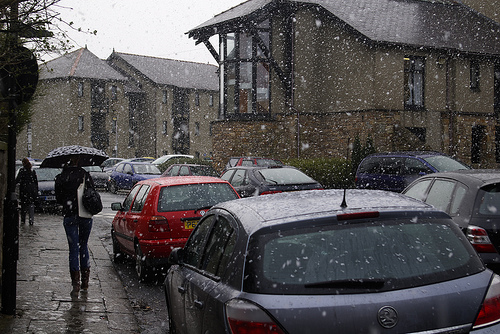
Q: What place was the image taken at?
A: It was taken at the street.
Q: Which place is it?
A: It is a street.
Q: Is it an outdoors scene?
A: Yes, it is outdoors.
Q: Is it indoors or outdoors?
A: It is outdoors.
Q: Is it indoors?
A: No, it is outdoors.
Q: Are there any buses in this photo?
A: No, there are no buses.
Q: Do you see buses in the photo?
A: No, there are no buses.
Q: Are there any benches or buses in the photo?
A: No, there are no buses or benches.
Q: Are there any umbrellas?
A: Yes, there is an umbrella.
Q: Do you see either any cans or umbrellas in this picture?
A: Yes, there is an umbrella.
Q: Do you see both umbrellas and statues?
A: No, there is an umbrella but no statues.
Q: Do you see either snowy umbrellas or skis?
A: Yes, there is a snowy umbrella.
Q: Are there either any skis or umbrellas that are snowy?
A: Yes, the umbrella is snowy.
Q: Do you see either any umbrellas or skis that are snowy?
A: Yes, the umbrella is snowy.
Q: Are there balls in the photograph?
A: No, there are no balls.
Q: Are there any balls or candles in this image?
A: No, there are no balls or candles.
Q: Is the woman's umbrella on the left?
A: Yes, the umbrella is on the left of the image.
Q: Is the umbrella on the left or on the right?
A: The umbrella is on the left of the image.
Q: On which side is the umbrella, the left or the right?
A: The umbrella is on the left of the image.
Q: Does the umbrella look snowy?
A: Yes, the umbrella is snowy.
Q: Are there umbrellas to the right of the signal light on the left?
A: Yes, there is an umbrella to the right of the traffic signal.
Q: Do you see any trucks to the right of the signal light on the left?
A: No, there is an umbrella to the right of the traffic signal.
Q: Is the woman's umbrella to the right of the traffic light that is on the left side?
A: Yes, the umbrella is to the right of the traffic signal.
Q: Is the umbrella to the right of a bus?
A: No, the umbrella is to the right of the traffic signal.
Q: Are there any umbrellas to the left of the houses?
A: Yes, there is an umbrella to the left of the houses.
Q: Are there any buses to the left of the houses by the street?
A: No, there is an umbrella to the left of the houses.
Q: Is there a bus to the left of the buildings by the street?
A: No, there is an umbrella to the left of the houses.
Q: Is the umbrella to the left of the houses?
A: Yes, the umbrella is to the left of the houses.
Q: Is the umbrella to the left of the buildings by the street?
A: Yes, the umbrella is to the left of the houses.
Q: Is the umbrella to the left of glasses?
A: No, the umbrella is to the left of the houses.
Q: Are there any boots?
A: Yes, there are boots.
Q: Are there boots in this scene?
A: Yes, there are boots.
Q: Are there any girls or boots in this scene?
A: Yes, there are boots.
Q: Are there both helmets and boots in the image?
A: No, there are boots but no helmets.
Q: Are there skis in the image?
A: No, there are no skis.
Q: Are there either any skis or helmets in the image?
A: No, there are no skis or helmets.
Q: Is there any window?
A: Yes, there is a window.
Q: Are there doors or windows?
A: Yes, there is a window.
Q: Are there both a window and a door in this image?
A: No, there is a window but no doors.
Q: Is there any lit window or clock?
A: Yes, there is a lit window.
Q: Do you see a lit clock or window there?
A: Yes, there is a lit window.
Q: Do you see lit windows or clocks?
A: Yes, there is a lit window.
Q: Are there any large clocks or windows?
A: Yes, there is a large window.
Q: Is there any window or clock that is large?
A: Yes, the window is large.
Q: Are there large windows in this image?
A: Yes, there is a large window.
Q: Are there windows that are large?
A: Yes, there is a window that is large.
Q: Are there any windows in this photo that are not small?
A: Yes, there is a large window.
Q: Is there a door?
A: No, there are no doors.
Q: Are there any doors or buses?
A: No, there are no doors or buses.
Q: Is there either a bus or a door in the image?
A: No, there are no doors or buses.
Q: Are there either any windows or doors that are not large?
A: No, there is a window but it is large.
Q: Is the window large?
A: Yes, the window is large.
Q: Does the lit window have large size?
A: Yes, the window is large.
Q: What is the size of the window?
A: The window is large.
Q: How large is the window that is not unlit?
A: The window is large.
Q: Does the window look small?
A: No, the window is large.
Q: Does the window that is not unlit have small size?
A: No, the window is large.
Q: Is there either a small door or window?
A: No, there is a window but it is large.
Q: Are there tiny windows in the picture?
A: No, there is a window but it is large.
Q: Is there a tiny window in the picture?
A: No, there is a window but it is large.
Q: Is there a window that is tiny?
A: No, there is a window but it is large.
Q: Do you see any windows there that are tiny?
A: No, there is a window but it is large.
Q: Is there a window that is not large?
A: No, there is a window but it is large.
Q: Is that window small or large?
A: The window is large.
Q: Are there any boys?
A: No, there are no boys.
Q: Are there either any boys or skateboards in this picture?
A: No, there are no boys or skateboards.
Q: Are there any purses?
A: Yes, there is a purse.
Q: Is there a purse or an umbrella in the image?
A: Yes, there is a purse.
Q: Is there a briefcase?
A: No, there are no briefcases.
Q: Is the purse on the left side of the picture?
A: Yes, the purse is on the left of the image.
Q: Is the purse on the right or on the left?
A: The purse is on the left of the image.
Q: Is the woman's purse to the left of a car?
A: Yes, the purse is to the left of a car.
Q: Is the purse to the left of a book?
A: No, the purse is to the left of a car.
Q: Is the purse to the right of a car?
A: No, the purse is to the left of a car.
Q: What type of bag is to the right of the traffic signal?
A: The bag is a purse.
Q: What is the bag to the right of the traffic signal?
A: The bag is a purse.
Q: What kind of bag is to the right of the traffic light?
A: The bag is a purse.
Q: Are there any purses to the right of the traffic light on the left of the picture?
A: Yes, there is a purse to the right of the traffic signal.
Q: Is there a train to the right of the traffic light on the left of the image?
A: No, there is a purse to the right of the traffic light.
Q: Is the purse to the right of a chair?
A: No, the purse is to the right of the traffic light.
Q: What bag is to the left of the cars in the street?
A: The bag is a purse.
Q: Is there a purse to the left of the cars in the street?
A: Yes, there is a purse to the left of the cars.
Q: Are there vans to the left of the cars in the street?
A: No, there is a purse to the left of the cars.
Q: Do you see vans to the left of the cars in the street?
A: No, there is a purse to the left of the cars.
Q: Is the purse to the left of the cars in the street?
A: Yes, the purse is to the left of the cars.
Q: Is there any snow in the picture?
A: Yes, there is snow.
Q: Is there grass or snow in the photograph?
A: Yes, there is snow.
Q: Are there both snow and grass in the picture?
A: No, there is snow but no grass.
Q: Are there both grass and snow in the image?
A: No, there is snow but no grass.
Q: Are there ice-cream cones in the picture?
A: No, there are no ice-cream cones.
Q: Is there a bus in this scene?
A: No, there are no buses.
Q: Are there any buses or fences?
A: No, there are no buses or fences.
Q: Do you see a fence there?
A: No, there are no fences.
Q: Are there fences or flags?
A: No, there are no fences or flags.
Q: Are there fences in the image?
A: No, there are no fences.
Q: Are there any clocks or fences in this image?
A: No, there are no fences or clocks.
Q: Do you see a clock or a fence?
A: No, there are no fences or clocks.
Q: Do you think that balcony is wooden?
A: Yes, the balcony is wooden.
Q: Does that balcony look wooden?
A: Yes, the balcony is wooden.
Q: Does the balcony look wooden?
A: Yes, the balcony is wooden.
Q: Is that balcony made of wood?
A: Yes, the balcony is made of wood.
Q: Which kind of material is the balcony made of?
A: The balcony is made of wood.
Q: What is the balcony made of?
A: The balcony is made of wood.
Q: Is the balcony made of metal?
A: No, the balcony is made of wood.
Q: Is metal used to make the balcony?
A: No, the balcony is made of wood.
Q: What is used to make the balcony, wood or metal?
A: The balcony is made of wood.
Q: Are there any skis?
A: No, there are no skis.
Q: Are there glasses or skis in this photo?
A: No, there are no skis or glasses.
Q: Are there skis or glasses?
A: No, there are no skis or glasses.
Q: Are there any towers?
A: No, there are no towers.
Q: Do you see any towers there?
A: No, there are no towers.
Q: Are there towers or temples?
A: No, there are no towers or temples.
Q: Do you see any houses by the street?
A: Yes, there are houses by the street.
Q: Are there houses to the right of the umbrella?
A: Yes, there are houses to the right of the umbrella.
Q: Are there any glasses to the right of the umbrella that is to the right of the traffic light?
A: No, there are houses to the right of the umbrella.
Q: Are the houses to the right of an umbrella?
A: Yes, the houses are to the right of an umbrella.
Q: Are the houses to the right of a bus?
A: No, the houses are to the right of an umbrella.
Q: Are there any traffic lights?
A: Yes, there is a traffic light.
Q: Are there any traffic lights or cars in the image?
A: Yes, there is a traffic light.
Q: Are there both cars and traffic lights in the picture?
A: Yes, there are both a traffic light and a car.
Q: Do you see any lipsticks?
A: No, there are no lipsticks.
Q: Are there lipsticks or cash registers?
A: No, there are no lipsticks or cash registers.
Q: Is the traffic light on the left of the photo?
A: Yes, the traffic light is on the left of the image.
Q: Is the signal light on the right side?
A: No, the signal light is on the left of the image.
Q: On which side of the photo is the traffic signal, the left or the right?
A: The traffic signal is on the left of the image.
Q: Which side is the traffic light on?
A: The traffic light is on the left of the image.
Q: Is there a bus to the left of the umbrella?
A: No, there is a traffic light to the left of the umbrella.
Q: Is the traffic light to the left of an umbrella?
A: Yes, the traffic light is to the left of an umbrella.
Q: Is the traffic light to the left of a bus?
A: No, the traffic light is to the left of an umbrella.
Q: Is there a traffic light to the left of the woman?
A: Yes, there is a traffic light to the left of the woman.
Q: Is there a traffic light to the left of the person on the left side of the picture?
A: Yes, there is a traffic light to the left of the woman.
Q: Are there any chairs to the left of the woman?
A: No, there is a traffic light to the left of the woman.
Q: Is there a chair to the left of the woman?
A: No, there is a traffic light to the left of the woman.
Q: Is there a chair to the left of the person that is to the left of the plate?
A: No, there is a traffic light to the left of the woman.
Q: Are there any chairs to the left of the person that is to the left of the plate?
A: No, there is a traffic light to the left of the woman.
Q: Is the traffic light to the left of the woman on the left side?
A: Yes, the traffic light is to the left of the woman.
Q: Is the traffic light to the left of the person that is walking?
A: Yes, the traffic light is to the left of the woman.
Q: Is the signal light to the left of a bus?
A: No, the signal light is to the left of the woman.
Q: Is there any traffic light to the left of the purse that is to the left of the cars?
A: Yes, there is a traffic light to the left of the purse.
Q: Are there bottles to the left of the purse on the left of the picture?
A: No, there is a traffic light to the left of the purse.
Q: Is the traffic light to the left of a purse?
A: Yes, the traffic light is to the left of a purse.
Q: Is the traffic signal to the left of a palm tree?
A: No, the traffic signal is to the left of a purse.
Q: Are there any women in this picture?
A: Yes, there is a woman.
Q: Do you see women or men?
A: Yes, there is a woman.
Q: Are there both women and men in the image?
A: No, there is a woman but no men.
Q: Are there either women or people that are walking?
A: Yes, the woman is walking.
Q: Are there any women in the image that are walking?
A: Yes, there is a woman that is walking.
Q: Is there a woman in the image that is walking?
A: Yes, there is a woman that is walking.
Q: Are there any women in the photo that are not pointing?
A: Yes, there is a woman that is walking.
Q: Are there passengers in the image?
A: No, there are no passengers.